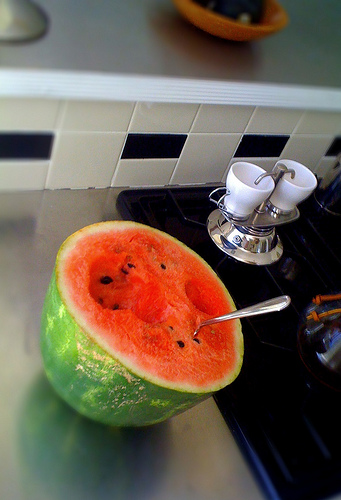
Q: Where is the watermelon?
A: On the counter.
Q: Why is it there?
A: To eat.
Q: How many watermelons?
A: 1.